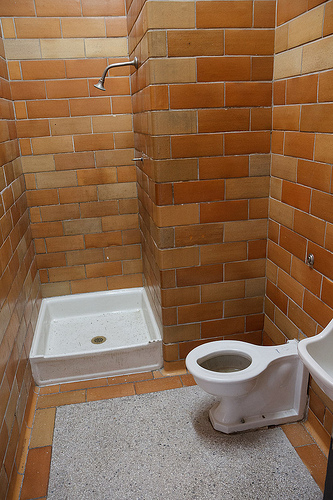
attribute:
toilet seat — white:
[179, 334, 287, 404]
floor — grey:
[67, 407, 198, 482]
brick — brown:
[155, 158, 195, 181]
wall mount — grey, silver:
[90, 56, 131, 93]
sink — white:
[294, 315, 332, 391]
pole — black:
[320, 427, 332, 498]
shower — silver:
[2, 51, 154, 365]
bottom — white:
[42, 298, 148, 353]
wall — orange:
[149, 45, 252, 168]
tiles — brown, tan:
[166, 33, 256, 125]